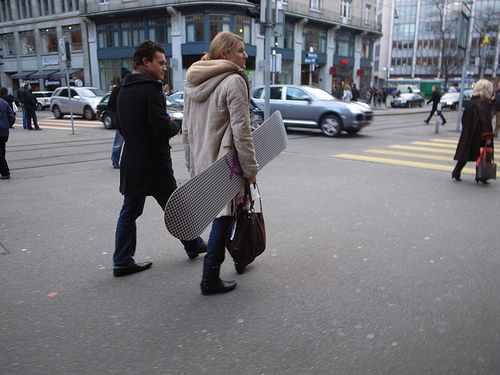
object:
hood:
[186, 60, 238, 88]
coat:
[182, 55, 259, 221]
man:
[424, 86, 446, 126]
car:
[247, 83, 373, 137]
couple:
[107, 31, 258, 296]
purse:
[230, 180, 267, 273]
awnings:
[12, 70, 40, 80]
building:
[0, 0, 396, 113]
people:
[180, 32, 267, 296]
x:
[224, 154, 243, 182]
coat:
[453, 96, 492, 160]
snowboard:
[163, 109, 288, 241]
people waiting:
[16, 83, 47, 128]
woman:
[450, 79, 493, 186]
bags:
[473, 139, 498, 181]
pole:
[64, 37, 72, 71]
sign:
[58, 37, 67, 64]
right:
[348, 0, 499, 373]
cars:
[50, 86, 114, 120]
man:
[105, 40, 208, 279]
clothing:
[109, 71, 183, 198]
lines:
[330, 153, 499, 178]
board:
[163, 110, 288, 241]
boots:
[200, 259, 238, 295]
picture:
[0, 0, 499, 374]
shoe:
[113, 259, 151, 279]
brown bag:
[477, 145, 499, 182]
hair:
[198, 31, 248, 63]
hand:
[249, 177, 260, 183]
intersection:
[3, 109, 498, 237]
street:
[0, 111, 497, 374]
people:
[13, 84, 30, 130]